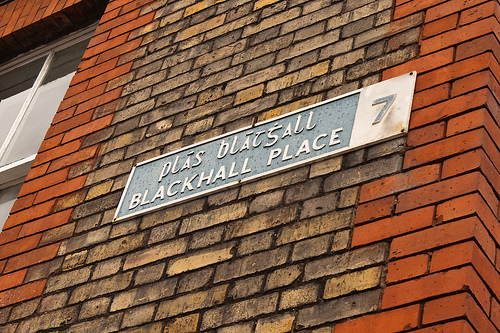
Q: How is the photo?
A: Clear.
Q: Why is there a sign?
A: Notification.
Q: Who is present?
A: No one.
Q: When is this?
A: Daytime.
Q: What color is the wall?
A: Brown.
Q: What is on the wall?
A: Sign.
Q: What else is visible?
A: Window.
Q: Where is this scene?
A: Near sign.